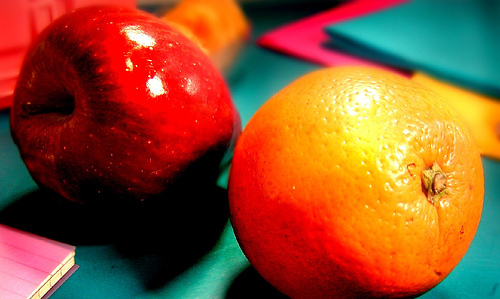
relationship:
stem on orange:
[423, 165, 448, 197] [222, 43, 487, 295]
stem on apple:
[19, 95, 75, 118] [1, 3, 246, 238]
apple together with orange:
[9, 2, 241, 204] [222, 43, 487, 295]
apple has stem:
[9, 2, 241, 204] [21, 97, 64, 118]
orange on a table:
[222, 43, 487, 295] [1, 1, 498, 297]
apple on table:
[9, 2, 241, 204] [1, 1, 498, 297]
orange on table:
[222, 43, 487, 295] [1, 1, 498, 297]